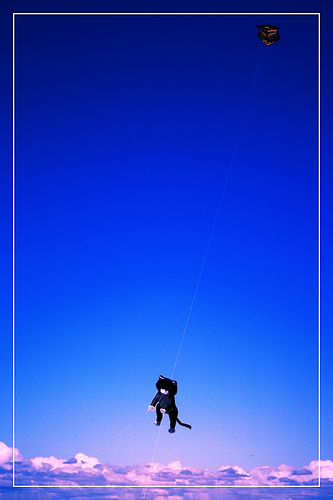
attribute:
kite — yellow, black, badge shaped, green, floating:
[258, 22, 282, 51]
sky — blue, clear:
[3, 0, 324, 499]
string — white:
[172, 48, 260, 379]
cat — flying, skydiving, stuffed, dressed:
[150, 377, 194, 435]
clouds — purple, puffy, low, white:
[2, 438, 332, 500]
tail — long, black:
[175, 413, 193, 431]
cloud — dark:
[1, 465, 104, 500]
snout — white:
[159, 385, 172, 397]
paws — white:
[148, 404, 165, 415]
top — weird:
[1, 4, 332, 141]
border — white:
[12, 11, 321, 492]